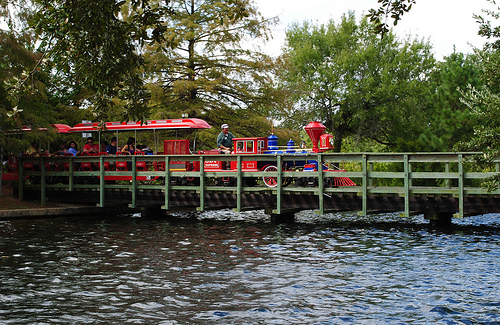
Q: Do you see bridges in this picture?
A: Yes, there is a bridge.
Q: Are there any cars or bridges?
A: Yes, there is a bridge.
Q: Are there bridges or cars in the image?
A: Yes, there is a bridge.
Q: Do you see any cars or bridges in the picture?
A: Yes, there is a bridge.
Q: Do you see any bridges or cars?
A: Yes, there is a bridge.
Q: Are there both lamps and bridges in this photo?
A: No, there is a bridge but no lamps.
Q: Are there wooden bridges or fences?
A: Yes, there is a wood bridge.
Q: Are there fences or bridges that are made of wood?
A: Yes, the bridge is made of wood.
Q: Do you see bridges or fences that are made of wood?
A: Yes, the bridge is made of wood.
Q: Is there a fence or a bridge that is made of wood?
A: Yes, the bridge is made of wood.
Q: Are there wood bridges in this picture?
A: Yes, there is a wood bridge.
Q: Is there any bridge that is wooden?
A: Yes, there is a bridge that is wooden.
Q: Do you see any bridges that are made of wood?
A: Yes, there is a bridge that is made of wood.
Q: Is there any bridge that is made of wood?
A: Yes, there is a bridge that is made of wood.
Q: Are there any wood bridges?
A: Yes, there is a bridge that is made of wood.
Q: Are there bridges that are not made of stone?
A: Yes, there is a bridge that is made of wood.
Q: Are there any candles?
A: No, there are no candles.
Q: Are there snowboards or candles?
A: No, there are no candles or snowboards.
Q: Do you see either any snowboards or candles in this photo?
A: No, there are no candles or snowboards.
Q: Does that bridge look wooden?
A: Yes, the bridge is wooden.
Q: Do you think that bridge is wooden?
A: Yes, the bridge is wooden.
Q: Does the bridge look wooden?
A: Yes, the bridge is wooden.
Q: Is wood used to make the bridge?
A: Yes, the bridge is made of wood.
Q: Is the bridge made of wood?
A: Yes, the bridge is made of wood.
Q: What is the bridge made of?
A: The bridge is made of wood.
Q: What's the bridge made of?
A: The bridge is made of wood.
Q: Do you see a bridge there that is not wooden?
A: No, there is a bridge but it is wooden.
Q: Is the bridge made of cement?
A: No, the bridge is made of wood.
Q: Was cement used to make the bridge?
A: No, the bridge is made of wood.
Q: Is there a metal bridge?
A: No, there is a bridge but it is made of wood.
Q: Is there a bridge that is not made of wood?
A: No, there is a bridge but it is made of wood.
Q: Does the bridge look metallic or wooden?
A: The bridge is wooden.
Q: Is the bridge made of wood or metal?
A: The bridge is made of wood.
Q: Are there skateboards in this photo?
A: No, there are no skateboards.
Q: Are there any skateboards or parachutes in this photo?
A: No, there are no skateboards or parachutes.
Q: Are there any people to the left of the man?
A: Yes, there are people to the left of the man.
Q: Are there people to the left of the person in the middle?
A: Yes, there are people to the left of the man.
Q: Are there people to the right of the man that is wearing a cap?
A: No, the people are to the left of the man.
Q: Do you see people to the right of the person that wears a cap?
A: No, the people are to the left of the man.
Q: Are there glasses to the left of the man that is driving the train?
A: No, there are people to the left of the man.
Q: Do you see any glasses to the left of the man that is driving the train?
A: No, there are people to the left of the man.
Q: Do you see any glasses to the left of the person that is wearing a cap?
A: No, there are people to the left of the man.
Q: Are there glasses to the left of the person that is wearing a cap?
A: No, there are people to the left of the man.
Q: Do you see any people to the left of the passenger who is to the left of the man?
A: Yes, there are people to the left of the passenger.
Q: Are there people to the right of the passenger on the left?
A: No, the people are to the left of the passenger.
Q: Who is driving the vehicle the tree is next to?
A: The man is driving the train.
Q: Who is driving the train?
A: The man is driving the train.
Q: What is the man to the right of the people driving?
A: The man is driving the train.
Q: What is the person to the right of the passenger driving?
A: The man is driving the train.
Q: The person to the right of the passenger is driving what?
A: The man is driving the train.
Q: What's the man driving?
A: The man is driving the train.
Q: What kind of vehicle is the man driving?
A: The man is driving the train.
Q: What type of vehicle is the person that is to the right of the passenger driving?
A: The man is driving the train.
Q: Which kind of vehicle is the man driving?
A: The man is driving the train.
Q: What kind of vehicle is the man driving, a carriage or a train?
A: The man is driving a train.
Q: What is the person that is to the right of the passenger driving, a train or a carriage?
A: The man is driving a train.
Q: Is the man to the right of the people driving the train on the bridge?
A: Yes, the man is driving the train.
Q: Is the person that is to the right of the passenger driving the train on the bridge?
A: Yes, the man is driving the train.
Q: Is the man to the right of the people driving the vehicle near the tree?
A: Yes, the man is driving the train.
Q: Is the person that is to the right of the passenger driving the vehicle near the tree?
A: Yes, the man is driving the train.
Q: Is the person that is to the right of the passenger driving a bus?
A: No, the man is driving the train.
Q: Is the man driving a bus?
A: No, the man is driving the train.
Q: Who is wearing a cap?
A: The man is wearing a cap.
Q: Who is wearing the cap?
A: The man is wearing a cap.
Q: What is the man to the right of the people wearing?
A: The man is wearing a cap.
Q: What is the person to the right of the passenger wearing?
A: The man is wearing a cap.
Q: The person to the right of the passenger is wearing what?
A: The man is wearing a cap.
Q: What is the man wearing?
A: The man is wearing a cap.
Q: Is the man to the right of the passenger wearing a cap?
A: Yes, the man is wearing a cap.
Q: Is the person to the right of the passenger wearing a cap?
A: Yes, the man is wearing a cap.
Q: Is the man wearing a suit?
A: No, the man is wearing a cap.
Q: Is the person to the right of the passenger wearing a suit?
A: No, the man is wearing a cap.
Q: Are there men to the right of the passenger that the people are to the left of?
A: Yes, there is a man to the right of the passenger.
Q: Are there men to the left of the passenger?
A: No, the man is to the right of the passenger.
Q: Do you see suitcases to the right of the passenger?
A: No, there is a man to the right of the passenger.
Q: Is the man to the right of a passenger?
A: Yes, the man is to the right of a passenger.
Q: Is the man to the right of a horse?
A: No, the man is to the right of a passenger.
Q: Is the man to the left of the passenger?
A: No, the man is to the right of the passenger.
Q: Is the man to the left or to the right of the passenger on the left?
A: The man is to the right of the passenger.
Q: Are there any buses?
A: No, there are no buses.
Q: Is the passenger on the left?
A: Yes, the passenger is on the left of the image.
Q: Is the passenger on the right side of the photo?
A: No, the passenger is on the left of the image.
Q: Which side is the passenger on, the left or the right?
A: The passenger is on the left of the image.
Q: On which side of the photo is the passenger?
A: The passenger is on the left of the image.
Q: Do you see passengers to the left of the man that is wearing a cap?
A: Yes, there is a passenger to the left of the man.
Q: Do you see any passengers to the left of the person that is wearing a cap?
A: Yes, there is a passenger to the left of the man.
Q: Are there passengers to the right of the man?
A: No, the passenger is to the left of the man.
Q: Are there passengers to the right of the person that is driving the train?
A: No, the passenger is to the left of the man.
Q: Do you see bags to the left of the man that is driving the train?
A: No, there is a passenger to the left of the man.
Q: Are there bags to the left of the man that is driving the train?
A: No, there is a passenger to the left of the man.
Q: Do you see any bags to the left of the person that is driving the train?
A: No, there is a passenger to the left of the man.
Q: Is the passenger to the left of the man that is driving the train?
A: Yes, the passenger is to the left of the man.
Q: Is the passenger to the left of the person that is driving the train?
A: Yes, the passenger is to the left of the man.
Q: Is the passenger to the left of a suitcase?
A: No, the passenger is to the left of the man.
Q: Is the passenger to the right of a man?
A: No, the passenger is to the left of a man.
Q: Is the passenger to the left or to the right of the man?
A: The passenger is to the left of the man.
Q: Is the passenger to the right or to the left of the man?
A: The passenger is to the left of the man.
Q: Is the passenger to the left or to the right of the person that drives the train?
A: The passenger is to the left of the man.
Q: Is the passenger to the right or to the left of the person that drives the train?
A: The passenger is to the left of the man.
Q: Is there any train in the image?
A: Yes, there is a train.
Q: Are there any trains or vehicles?
A: Yes, there is a train.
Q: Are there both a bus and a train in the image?
A: No, there is a train but no buses.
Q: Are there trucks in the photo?
A: No, there are no trucks.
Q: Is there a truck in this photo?
A: No, there are no trucks.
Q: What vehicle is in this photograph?
A: The vehicle is a train.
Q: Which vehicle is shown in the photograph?
A: The vehicle is a train.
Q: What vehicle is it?
A: The vehicle is a train.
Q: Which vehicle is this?
A: This is a train.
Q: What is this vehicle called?
A: This is a train.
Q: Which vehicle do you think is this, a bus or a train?
A: This is a train.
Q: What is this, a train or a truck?
A: This is a train.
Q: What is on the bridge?
A: The train is on the bridge.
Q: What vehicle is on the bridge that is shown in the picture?
A: The vehicle is a train.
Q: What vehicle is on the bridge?
A: The vehicle is a train.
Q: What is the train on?
A: The train is on the bridge.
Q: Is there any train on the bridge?
A: Yes, there is a train on the bridge.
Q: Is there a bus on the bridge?
A: No, there is a train on the bridge.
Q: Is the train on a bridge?
A: Yes, the train is on a bridge.